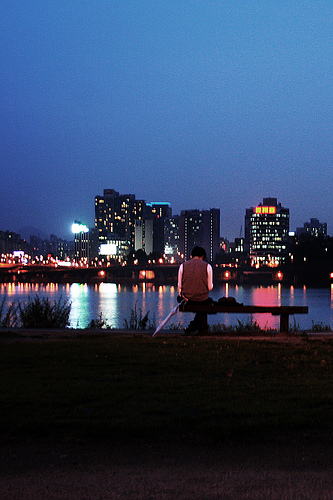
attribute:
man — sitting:
[166, 241, 224, 329]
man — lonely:
[174, 242, 218, 334]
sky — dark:
[3, 2, 331, 217]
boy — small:
[176, 243, 216, 332]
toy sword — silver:
[151, 297, 183, 337]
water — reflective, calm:
[0, 281, 332, 329]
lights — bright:
[69, 217, 91, 235]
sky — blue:
[9, 69, 332, 189]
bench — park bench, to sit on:
[180, 303, 308, 332]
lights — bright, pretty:
[2, 198, 332, 280]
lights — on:
[47, 187, 198, 263]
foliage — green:
[6, 294, 71, 328]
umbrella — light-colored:
[152, 296, 189, 336]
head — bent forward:
[183, 241, 224, 262]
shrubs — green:
[0, 293, 75, 329]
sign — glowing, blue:
[69, 218, 90, 234]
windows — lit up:
[249, 199, 278, 214]